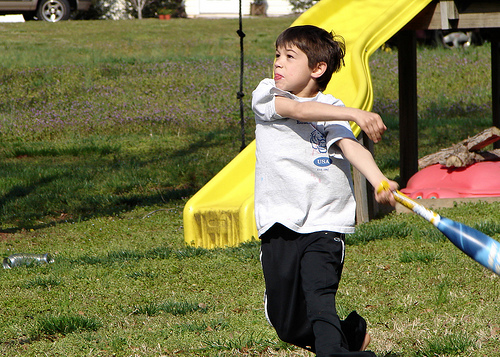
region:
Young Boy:
[251, 19, 398, 355]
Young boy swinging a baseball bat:
[250, 19, 499, 355]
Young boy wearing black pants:
[249, 24, 400, 355]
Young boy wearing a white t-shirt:
[247, 21, 397, 356]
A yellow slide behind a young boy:
[179, 0, 439, 354]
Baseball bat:
[378, 178, 499, 287]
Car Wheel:
[36, 0, 71, 24]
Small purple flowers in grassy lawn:
[0, 57, 226, 161]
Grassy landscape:
[2, 275, 244, 356]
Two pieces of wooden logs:
[416, 125, 499, 170]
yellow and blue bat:
[378, 181, 499, 274]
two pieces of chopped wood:
[416, 126, 498, 168]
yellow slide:
[183, 1, 426, 248]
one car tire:
[37, 0, 69, 23]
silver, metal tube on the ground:
[5, 251, 53, 269]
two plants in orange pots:
[155, 7, 172, 20]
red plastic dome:
[397, 158, 499, 204]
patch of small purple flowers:
[11, 51, 483, 133]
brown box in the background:
[248, 2, 264, 14]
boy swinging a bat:
[251, 23, 398, 348]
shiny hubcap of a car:
[41, 4, 68, 21]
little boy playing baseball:
[251, 17, 499, 328]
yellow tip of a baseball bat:
[376, 172, 443, 227]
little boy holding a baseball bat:
[252, 29, 494, 299]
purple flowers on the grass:
[56, 45, 224, 141]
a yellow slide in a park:
[336, 2, 429, 102]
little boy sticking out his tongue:
[260, 22, 340, 114]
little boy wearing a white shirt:
[247, 18, 367, 231]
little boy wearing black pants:
[261, 225, 380, 340]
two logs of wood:
[424, 117, 496, 169]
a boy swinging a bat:
[234, 20, 498, 350]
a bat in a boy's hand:
[370, 164, 498, 269]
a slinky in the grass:
[0, 242, 53, 278]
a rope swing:
[224, 1, 273, 161]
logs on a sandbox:
[413, 108, 498, 175]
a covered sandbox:
[397, 153, 497, 214]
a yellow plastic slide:
[184, 1, 450, 247]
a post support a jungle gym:
[392, 32, 427, 187]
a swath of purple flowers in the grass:
[4, 45, 262, 127]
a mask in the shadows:
[436, 29, 478, 50]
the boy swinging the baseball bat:
[196, 23, 417, 340]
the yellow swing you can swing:
[260, 5, 455, 21]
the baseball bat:
[366, 180, 498, 263]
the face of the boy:
[269, 37, 369, 88]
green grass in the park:
[64, 20, 184, 162]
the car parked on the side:
[1, 1, 138, 21]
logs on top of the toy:
[399, 140, 496, 175]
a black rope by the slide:
[226, 13, 248, 156]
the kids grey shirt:
[232, 131, 362, 195]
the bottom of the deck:
[442, 3, 465, 40]